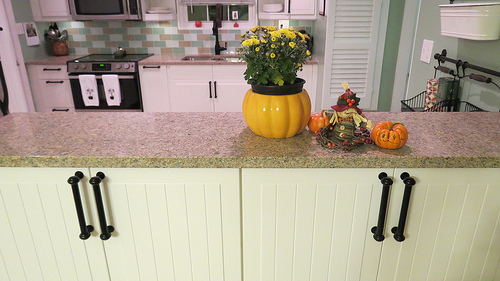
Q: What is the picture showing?
A: It is showing a kitchen.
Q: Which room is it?
A: It is a kitchen.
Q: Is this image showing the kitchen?
A: Yes, it is showing the kitchen.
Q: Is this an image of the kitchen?
A: Yes, it is showing the kitchen.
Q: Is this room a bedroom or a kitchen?
A: It is a kitchen.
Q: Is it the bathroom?
A: No, it is the kitchen.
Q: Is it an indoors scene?
A: Yes, it is indoors.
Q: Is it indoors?
A: Yes, it is indoors.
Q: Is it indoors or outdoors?
A: It is indoors.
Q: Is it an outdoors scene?
A: No, it is indoors.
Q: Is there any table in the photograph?
A: No, there are no tables.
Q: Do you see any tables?
A: No, there are no tables.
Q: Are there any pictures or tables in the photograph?
A: No, there are no tables or pictures.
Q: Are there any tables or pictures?
A: No, there are no tables or pictures.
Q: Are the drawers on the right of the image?
A: No, the drawers are on the left of the image.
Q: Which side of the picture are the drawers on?
A: The drawers are on the left of the image.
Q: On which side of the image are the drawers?
A: The drawers are on the left of the image.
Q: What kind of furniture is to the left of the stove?
A: The pieces of furniture are drawers.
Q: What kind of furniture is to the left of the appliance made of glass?
A: The pieces of furniture are drawers.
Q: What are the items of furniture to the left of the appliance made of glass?
A: The pieces of furniture are drawers.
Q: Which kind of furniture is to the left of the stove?
A: The pieces of furniture are drawers.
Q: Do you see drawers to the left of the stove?
A: Yes, there are drawers to the left of the stove.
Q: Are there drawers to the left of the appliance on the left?
A: Yes, there are drawers to the left of the stove.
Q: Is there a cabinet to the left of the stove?
A: No, there are drawers to the left of the stove.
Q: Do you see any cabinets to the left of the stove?
A: No, there are drawers to the left of the stove.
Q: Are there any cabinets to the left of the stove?
A: No, there are drawers to the left of the stove.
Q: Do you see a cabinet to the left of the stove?
A: No, there are drawers to the left of the stove.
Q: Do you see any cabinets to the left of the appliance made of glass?
A: No, there are drawers to the left of the stove.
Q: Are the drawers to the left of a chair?
A: No, the drawers are to the left of the stove.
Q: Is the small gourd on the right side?
A: Yes, the gourd is on the right of the image.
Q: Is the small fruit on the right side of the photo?
A: Yes, the gourd is on the right of the image.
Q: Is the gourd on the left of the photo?
A: No, the gourd is on the right of the image.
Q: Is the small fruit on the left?
A: No, the gourd is on the right of the image.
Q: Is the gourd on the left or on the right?
A: The gourd is on the right of the image.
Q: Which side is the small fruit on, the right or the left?
A: The gourd is on the right of the image.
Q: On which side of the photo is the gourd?
A: The gourd is on the right of the image.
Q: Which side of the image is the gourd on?
A: The gourd is on the right of the image.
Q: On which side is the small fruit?
A: The gourd is on the right of the image.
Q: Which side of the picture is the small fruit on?
A: The gourd is on the right of the image.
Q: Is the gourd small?
A: Yes, the gourd is small.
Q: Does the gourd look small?
A: Yes, the gourd is small.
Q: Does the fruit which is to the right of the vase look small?
A: Yes, the gourd is small.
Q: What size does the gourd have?
A: The gourd has small size.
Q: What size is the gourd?
A: The gourd is small.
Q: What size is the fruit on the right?
A: The gourd is small.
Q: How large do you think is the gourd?
A: The gourd is small.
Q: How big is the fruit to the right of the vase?
A: The gourd is small.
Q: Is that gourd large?
A: No, the gourd is small.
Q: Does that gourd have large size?
A: No, the gourd is small.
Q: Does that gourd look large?
A: No, the gourd is small.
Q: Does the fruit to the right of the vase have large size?
A: No, the gourd is small.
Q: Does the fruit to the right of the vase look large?
A: No, the gourd is small.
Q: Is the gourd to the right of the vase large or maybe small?
A: The gourd is small.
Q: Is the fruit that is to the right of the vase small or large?
A: The gourd is small.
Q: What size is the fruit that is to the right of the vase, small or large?
A: The gourd is small.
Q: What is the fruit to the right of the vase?
A: The fruit is a gourd.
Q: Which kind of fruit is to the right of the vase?
A: The fruit is a gourd.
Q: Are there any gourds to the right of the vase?
A: Yes, there is a gourd to the right of the vase.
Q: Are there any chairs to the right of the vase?
A: No, there is a gourd to the right of the vase.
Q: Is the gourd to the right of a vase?
A: Yes, the gourd is to the right of a vase.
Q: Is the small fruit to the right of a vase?
A: Yes, the gourd is to the right of a vase.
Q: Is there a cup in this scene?
A: No, there are no cups.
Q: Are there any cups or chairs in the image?
A: No, there are no cups or chairs.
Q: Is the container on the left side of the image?
A: Yes, the container is on the left of the image.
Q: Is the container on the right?
A: No, the container is on the left of the image.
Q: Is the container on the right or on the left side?
A: The container is on the left of the image.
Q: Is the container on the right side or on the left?
A: The container is on the left of the image.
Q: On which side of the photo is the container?
A: The container is on the left of the image.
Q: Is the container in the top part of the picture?
A: Yes, the container is in the top of the image.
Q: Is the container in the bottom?
A: No, the container is in the top of the image.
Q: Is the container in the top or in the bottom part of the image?
A: The container is in the top of the image.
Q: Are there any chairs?
A: No, there are no chairs.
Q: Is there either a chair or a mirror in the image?
A: No, there are no chairs or mirrors.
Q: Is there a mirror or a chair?
A: No, there are no chairs or mirrors.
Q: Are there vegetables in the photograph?
A: Yes, there are vegetables.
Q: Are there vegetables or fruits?
A: Yes, there are vegetables.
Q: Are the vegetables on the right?
A: Yes, the vegetables are on the right of the image.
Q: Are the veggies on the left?
A: No, the veggies are on the right of the image.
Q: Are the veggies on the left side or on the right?
A: The veggies are on the right of the image.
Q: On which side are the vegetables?
A: The vegetables are on the right of the image.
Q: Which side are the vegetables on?
A: The vegetables are on the right of the image.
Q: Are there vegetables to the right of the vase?
A: Yes, there are vegetables to the right of the vase.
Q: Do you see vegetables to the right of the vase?
A: Yes, there are vegetables to the right of the vase.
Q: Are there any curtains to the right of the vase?
A: No, there are vegetables to the right of the vase.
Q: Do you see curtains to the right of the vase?
A: No, there are vegetables to the right of the vase.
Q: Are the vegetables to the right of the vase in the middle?
A: Yes, the vegetables are to the right of the vase.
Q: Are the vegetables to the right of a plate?
A: No, the vegetables are to the right of the vase.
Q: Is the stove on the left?
A: Yes, the stove is on the left of the image.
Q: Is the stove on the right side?
A: No, the stove is on the left of the image.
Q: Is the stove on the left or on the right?
A: The stove is on the left of the image.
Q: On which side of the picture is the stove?
A: The stove is on the left of the image.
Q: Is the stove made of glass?
A: Yes, the stove is made of glass.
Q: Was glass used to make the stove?
A: Yes, the stove is made of glass.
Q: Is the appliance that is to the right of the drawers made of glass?
A: Yes, the stove is made of glass.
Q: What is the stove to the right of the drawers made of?
A: The stove is made of glass.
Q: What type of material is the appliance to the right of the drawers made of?
A: The stove is made of glass.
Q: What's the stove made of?
A: The stove is made of glass.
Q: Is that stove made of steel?
A: No, the stove is made of glass.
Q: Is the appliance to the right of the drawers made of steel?
A: No, the stove is made of glass.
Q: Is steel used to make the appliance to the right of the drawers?
A: No, the stove is made of glass.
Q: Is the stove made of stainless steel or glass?
A: The stove is made of glass.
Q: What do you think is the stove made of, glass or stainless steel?
A: The stove is made of glass.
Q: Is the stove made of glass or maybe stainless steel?
A: The stove is made of glass.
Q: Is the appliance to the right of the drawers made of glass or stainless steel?
A: The stove is made of glass.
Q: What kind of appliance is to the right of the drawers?
A: The appliance is a stove.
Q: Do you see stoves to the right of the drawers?
A: Yes, there is a stove to the right of the drawers.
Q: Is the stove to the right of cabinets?
A: No, the stove is to the right of the drawers.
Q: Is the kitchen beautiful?
A: Yes, the kitchen is beautiful.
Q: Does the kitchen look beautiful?
A: Yes, the kitchen is beautiful.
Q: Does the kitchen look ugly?
A: No, the kitchen is beautiful.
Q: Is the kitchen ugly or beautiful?
A: The kitchen is beautiful.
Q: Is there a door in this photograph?
A: Yes, there is a door.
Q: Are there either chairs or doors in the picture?
A: Yes, there is a door.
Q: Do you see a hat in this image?
A: Yes, there is a hat.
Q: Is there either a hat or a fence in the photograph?
A: Yes, there is a hat.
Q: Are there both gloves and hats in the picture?
A: No, there is a hat but no gloves.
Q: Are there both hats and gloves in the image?
A: No, there is a hat but no gloves.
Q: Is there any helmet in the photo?
A: No, there are no helmets.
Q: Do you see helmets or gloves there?
A: No, there are no helmets or gloves.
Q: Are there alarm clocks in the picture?
A: No, there are no alarm clocks.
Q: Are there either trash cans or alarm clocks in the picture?
A: No, there are no alarm clocks or trash cans.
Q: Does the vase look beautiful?
A: Yes, the vase is beautiful.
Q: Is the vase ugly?
A: No, the vase is beautiful.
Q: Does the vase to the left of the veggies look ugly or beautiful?
A: The vase is beautiful.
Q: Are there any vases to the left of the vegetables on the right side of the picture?
A: Yes, there is a vase to the left of the vegetables.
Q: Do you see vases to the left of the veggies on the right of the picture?
A: Yes, there is a vase to the left of the vegetables.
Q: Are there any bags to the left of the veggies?
A: No, there is a vase to the left of the veggies.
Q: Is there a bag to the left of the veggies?
A: No, there is a vase to the left of the veggies.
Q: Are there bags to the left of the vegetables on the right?
A: No, there is a vase to the left of the veggies.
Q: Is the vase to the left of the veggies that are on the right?
A: Yes, the vase is to the left of the veggies.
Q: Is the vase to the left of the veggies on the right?
A: Yes, the vase is to the left of the veggies.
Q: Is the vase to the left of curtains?
A: No, the vase is to the left of the veggies.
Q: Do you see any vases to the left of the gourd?
A: Yes, there is a vase to the left of the gourd.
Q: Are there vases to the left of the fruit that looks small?
A: Yes, there is a vase to the left of the gourd.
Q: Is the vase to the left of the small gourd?
A: Yes, the vase is to the left of the gourd.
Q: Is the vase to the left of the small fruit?
A: Yes, the vase is to the left of the gourd.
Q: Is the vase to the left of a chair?
A: No, the vase is to the left of the gourd.